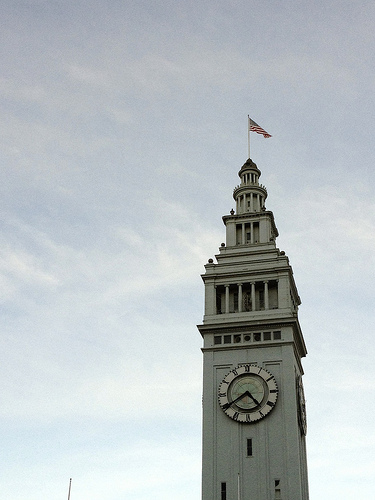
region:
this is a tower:
[231, 391, 287, 462]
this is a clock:
[167, 370, 323, 469]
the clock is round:
[224, 322, 245, 407]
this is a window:
[195, 304, 270, 314]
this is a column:
[243, 291, 258, 309]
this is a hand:
[229, 387, 236, 391]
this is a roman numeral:
[234, 377, 268, 419]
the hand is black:
[214, 393, 252, 418]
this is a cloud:
[92, 383, 123, 419]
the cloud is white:
[130, 432, 151, 470]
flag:
[238, 107, 285, 150]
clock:
[211, 358, 282, 423]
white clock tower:
[198, 143, 321, 491]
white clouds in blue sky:
[101, 385, 124, 410]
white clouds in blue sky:
[318, 422, 335, 440]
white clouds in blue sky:
[108, 385, 143, 415]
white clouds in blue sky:
[13, 393, 76, 440]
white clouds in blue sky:
[123, 433, 164, 471]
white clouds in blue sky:
[32, 274, 80, 300]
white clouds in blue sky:
[118, 318, 151, 346]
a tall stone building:
[150, 92, 340, 499]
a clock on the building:
[205, 343, 307, 452]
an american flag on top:
[227, 103, 284, 184]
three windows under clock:
[199, 433, 283, 498]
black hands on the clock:
[226, 384, 289, 411]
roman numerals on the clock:
[214, 347, 283, 433]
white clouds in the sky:
[24, 24, 362, 420]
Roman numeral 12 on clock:
[242, 361, 252, 376]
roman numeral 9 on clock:
[213, 386, 235, 401]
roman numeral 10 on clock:
[214, 375, 239, 390]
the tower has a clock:
[223, 365, 279, 423]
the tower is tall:
[196, 114, 307, 498]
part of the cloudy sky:
[1, 441, 49, 494]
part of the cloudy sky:
[1, 377, 74, 430]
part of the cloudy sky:
[131, 402, 177, 467]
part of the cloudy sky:
[139, 307, 172, 347]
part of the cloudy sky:
[70, 294, 108, 340]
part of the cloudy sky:
[14, 247, 50, 285]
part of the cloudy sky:
[316, 258, 356, 325]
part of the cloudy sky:
[328, 383, 352, 443]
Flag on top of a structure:
[246, 112, 272, 159]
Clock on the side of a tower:
[217, 364, 279, 424]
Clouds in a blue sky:
[2, 37, 373, 497]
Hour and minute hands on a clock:
[223, 390, 264, 412]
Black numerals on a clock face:
[243, 365, 251, 372]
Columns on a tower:
[249, 280, 257, 312]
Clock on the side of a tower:
[295, 375, 307, 435]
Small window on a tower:
[245, 434, 255, 459]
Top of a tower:
[234, 155, 267, 213]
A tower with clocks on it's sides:
[199, 113, 310, 498]